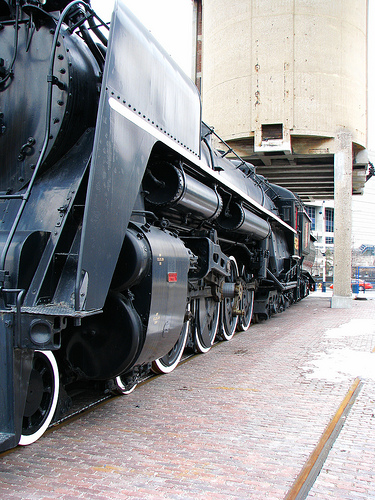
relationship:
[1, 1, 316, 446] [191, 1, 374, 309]
train under a siloh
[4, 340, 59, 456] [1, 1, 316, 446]
wheel on train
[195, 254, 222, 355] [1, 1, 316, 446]
wheel on train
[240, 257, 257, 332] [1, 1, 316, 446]
wheel on train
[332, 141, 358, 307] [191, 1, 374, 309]
pillar supporting siloh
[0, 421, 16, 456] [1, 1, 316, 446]
step on train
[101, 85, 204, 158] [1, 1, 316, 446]
rivets on train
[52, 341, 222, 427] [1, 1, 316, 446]
rail for train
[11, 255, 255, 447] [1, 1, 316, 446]
wheels on train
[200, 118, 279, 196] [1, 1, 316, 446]
rail on a train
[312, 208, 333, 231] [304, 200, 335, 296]
windows on building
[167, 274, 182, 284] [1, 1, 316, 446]
red spot on train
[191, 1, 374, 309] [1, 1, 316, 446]
siloh above train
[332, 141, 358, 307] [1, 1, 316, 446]
pillar by train